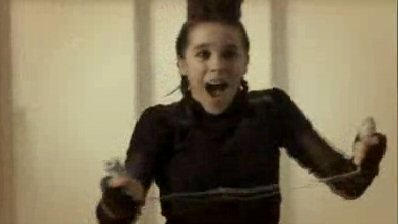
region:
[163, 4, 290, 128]
the head of a girl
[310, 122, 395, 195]
the hand of a girl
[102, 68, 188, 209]
the arm of a girl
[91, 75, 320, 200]
a girl wearing a shirt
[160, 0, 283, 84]
the hair of a girl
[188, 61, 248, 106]
the mouth of a girl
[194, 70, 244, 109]
the teeth of a girl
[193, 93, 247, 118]
the chin of a girl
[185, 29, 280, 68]
the eyes of a girl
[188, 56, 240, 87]
the nose of a girl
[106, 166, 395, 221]
The strings between the girls hands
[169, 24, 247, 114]
The girls suprised face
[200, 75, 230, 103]
The girls open mouth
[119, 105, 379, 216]
The girls black shirt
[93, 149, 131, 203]
The pole in the girls left hand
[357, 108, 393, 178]
The pole in the girls right hand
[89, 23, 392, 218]
A girl holding something in her hands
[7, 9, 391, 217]
The beige wall behind the girl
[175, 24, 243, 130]
The girls face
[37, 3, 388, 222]
A room with a girl in it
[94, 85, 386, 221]
long sleeve black shirt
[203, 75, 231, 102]
mouth hanging wide open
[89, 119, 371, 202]
spools of string or wire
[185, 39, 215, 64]
one open eye ball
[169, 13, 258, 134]
dark coloured hair in pig tails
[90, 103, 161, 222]
person's right hand and arm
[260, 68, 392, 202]
person's right hand and arm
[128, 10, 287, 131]
little girls head and shoulders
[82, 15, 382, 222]
little girl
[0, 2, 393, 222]
low resolution black and white still shot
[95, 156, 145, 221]
hand of a woman with a wii controller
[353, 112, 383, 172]
wii controller in a woman's hand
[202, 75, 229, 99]
a girl's open mouth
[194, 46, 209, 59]
eye of a young girl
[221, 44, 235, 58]
eye of a young girl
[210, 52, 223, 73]
nose of a young girl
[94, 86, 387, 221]
a girls sweater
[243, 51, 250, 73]
ear of a young girl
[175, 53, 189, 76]
ear of a girl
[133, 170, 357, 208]
wires between wii controller